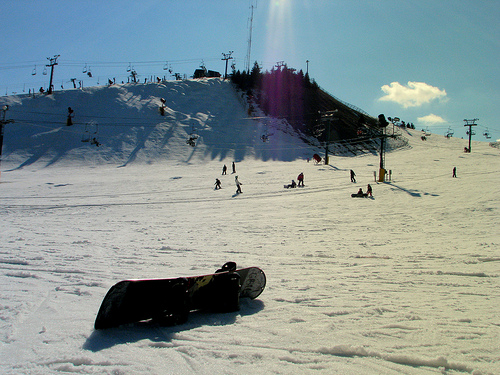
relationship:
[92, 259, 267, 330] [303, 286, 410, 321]
board on ground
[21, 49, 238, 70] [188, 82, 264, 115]
ski lifts above hill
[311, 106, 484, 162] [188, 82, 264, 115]
ski lifts in front of hill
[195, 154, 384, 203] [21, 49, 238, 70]
people near ski lifts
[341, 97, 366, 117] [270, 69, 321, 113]
fence near hill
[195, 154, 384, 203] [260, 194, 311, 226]
people are standing in snow area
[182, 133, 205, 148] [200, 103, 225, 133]
snowboarder going down hill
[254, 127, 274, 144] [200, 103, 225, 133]
snowboarder going down hill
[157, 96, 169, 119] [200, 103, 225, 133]
snowboarder going down hill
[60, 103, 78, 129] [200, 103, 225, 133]
snowboarder going down hill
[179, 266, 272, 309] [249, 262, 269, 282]
board has a edge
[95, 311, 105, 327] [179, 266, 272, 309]
tip of board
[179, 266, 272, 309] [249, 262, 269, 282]
board has an edge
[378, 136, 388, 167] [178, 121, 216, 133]
pole in snow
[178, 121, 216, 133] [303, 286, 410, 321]
snow on ground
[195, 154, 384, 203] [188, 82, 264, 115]
people on hill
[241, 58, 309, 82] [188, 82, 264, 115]
trees on hill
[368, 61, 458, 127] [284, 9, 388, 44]
clouds in sky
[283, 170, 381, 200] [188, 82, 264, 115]
skiers on hill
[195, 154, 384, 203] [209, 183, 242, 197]
people wearing skis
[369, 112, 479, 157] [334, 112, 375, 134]
poles holding up cables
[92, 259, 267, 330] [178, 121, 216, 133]
board left in snow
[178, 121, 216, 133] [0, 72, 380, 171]
snow on hill side